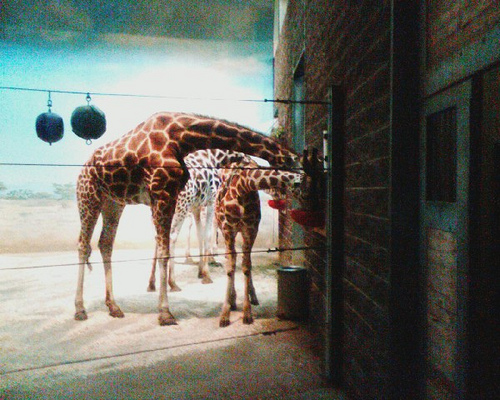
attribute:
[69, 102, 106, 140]
object — black, blue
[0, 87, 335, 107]
wire — metal, black, thin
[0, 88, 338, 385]
fence — wire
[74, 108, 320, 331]
giraffe — leaning, brown, white, feeding, yellow, standing, eating, adult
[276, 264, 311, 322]
container — round, grey, small, metal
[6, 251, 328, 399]
ground — sandy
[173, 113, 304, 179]
neck — long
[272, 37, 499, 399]
building — brick, brown, green, red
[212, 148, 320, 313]
giraffe — feeding, brown, yellow, standing, eating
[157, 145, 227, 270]
giraffe — feeding, standing, eating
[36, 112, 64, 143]
container — black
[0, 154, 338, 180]
wire — metal, black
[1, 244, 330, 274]
wire — metal, black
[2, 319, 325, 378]
wire — metal, black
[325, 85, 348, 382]
pole — metal, large, grey, thin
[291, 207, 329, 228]
tray — red, circular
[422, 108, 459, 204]
window — barred off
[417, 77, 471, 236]
framing — metal, gray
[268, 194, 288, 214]
bin — red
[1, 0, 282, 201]
sky — blue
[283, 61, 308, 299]
door — metal, grey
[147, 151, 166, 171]
spot — brown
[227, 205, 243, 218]
spot — brown